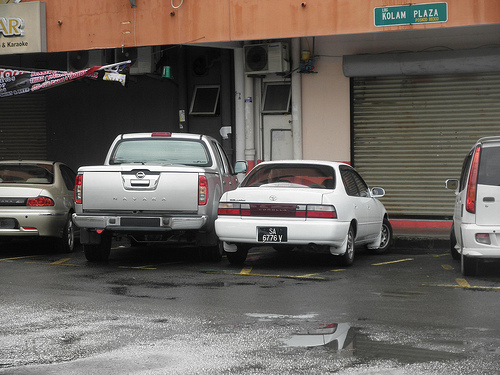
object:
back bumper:
[213, 215, 339, 247]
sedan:
[0, 160, 73, 248]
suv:
[446, 133, 498, 280]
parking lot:
[3, 25, 497, 373]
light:
[295, 206, 337, 219]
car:
[215, 159, 393, 266]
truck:
[73, 132, 247, 262]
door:
[340, 51, 500, 217]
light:
[198, 175, 209, 207]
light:
[74, 173, 83, 202]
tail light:
[218, 204, 252, 215]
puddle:
[323, 312, 439, 363]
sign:
[374, 2, 449, 26]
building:
[1, 0, 500, 244]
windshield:
[239, 162, 336, 187]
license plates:
[259, 227, 288, 244]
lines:
[300, 258, 415, 280]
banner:
[0, 60, 129, 104]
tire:
[371, 220, 394, 254]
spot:
[175, 211, 442, 307]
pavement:
[13, 222, 498, 369]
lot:
[6, 247, 498, 369]